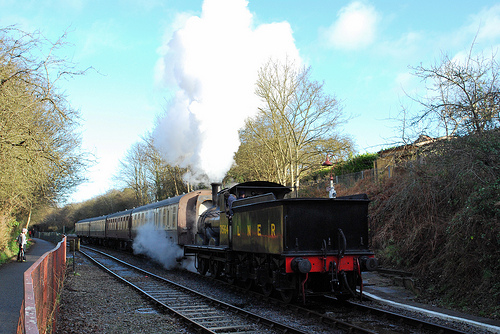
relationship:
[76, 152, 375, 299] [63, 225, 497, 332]
train on track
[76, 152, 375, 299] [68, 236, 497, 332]
train moving on tracks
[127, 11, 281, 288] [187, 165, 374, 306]
smoke coming from engine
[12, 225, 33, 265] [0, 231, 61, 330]
person standing on sidewalk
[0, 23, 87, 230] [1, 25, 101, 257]
leaves on tree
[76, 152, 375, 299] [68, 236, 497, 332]
train driving down tracks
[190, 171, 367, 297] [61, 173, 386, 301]
front car on train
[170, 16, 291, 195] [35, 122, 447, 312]
steam coming off top train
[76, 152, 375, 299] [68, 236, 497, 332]
train on tracks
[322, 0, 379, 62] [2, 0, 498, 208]
cloud in sky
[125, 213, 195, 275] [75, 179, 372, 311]
smoke coming out train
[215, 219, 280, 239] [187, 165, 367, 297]
writing on train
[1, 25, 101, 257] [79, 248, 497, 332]
tree on side of track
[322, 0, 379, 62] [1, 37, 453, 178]
cloud in sky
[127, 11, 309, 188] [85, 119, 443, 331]
smoke coming from train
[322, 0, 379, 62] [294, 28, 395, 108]
cloud in sky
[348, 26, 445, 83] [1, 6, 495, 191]
clouds in sky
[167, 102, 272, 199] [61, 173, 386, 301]
white smoke billowing out of train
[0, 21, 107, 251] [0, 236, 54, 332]
trees along sidewalk